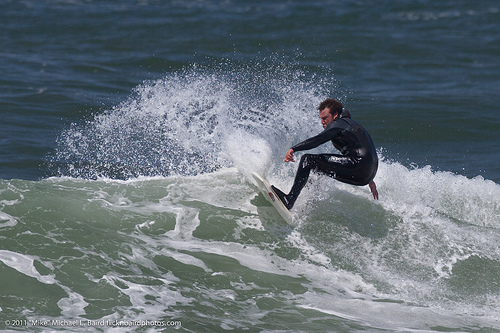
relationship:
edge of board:
[253, 172, 293, 225] [249, 172, 299, 229]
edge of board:
[254, 167, 292, 223] [251, 159, 323, 229]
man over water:
[269, 97, 378, 211] [49, 179, 474, 331]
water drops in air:
[152, 93, 224, 160] [4, 4, 498, 206]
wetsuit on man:
[262, 104, 396, 219] [264, 92, 391, 234]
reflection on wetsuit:
[302, 147, 373, 177] [266, 73, 406, 207]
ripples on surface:
[2, 0, 499, 181] [2, 0, 499, 331]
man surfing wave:
[271, 97, 379, 207] [6, 170, 499, 329]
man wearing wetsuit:
[269, 97, 378, 211] [273, 122, 378, 204]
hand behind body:
[370, 180, 380, 200] [277, 85, 380, 208]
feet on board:
[269, 182, 298, 209] [246, 167, 298, 226]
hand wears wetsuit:
[366, 180, 378, 200] [288, 115, 378, 210]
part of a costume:
[146, 302, 240, 317] [278, 117, 378, 200]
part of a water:
[99, 207, 216, 281] [387, 61, 487, 131]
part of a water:
[286, 276, 371, 319] [84, 15, 265, 83]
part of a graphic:
[87, 320, 117, 326] [3, 318, 180, 331]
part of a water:
[355, 291, 415, 316] [2, 3, 499, 331]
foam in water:
[192, 146, 466, 199] [45, 181, 208, 291]